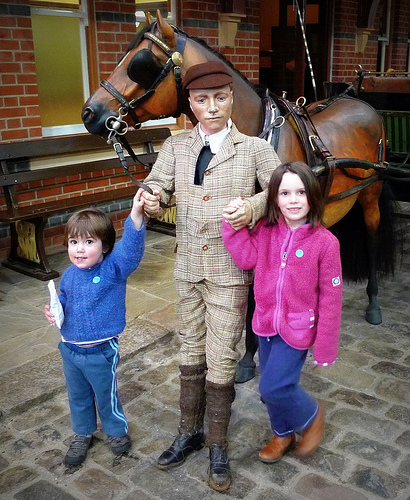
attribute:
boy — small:
[45, 186, 151, 469]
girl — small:
[216, 161, 344, 463]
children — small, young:
[37, 159, 348, 464]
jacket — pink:
[218, 213, 346, 369]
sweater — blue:
[53, 208, 154, 341]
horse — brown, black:
[84, 10, 393, 325]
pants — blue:
[53, 342, 133, 439]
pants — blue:
[248, 339, 318, 434]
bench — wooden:
[1, 121, 186, 283]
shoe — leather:
[296, 401, 331, 455]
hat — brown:
[180, 60, 232, 93]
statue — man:
[146, 68, 279, 489]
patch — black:
[125, 46, 169, 89]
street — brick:
[3, 278, 408, 496]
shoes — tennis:
[64, 422, 133, 466]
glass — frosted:
[28, 9, 96, 128]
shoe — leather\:
[260, 430, 293, 463]